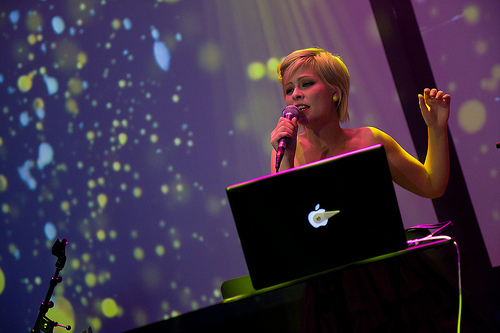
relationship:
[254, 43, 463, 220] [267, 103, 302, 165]
girl singing into microphone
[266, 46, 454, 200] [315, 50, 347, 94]
girl with hair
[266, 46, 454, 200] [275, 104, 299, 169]
girl holding microphone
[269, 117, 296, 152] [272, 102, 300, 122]
hand holding microphone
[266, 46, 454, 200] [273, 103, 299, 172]
girl singing into mic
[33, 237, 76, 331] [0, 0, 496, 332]
instrument on stage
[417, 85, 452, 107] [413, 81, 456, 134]
fingers on womans hand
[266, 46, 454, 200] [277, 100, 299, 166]
girl holding mic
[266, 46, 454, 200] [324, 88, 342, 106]
girl wearing earring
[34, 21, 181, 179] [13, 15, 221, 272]
dots on walls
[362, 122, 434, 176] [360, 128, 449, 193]
light on arm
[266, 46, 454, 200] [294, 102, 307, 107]
girl has teeth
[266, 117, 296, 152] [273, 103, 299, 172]
hand holding mic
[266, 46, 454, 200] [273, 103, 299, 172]
girl holding mic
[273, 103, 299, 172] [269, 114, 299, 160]
mic in hand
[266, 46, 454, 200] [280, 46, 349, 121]
girl with hair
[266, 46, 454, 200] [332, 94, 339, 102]
girl with earrings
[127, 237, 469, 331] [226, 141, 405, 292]
table with black laptop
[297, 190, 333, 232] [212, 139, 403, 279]
apple logo on black laptop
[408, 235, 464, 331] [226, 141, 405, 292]
wire on black laptop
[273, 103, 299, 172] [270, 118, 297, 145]
mic in hand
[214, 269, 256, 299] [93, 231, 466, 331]
chair in front of table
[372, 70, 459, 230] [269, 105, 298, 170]
hand holding microphone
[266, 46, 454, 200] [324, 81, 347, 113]
girl wearing earring